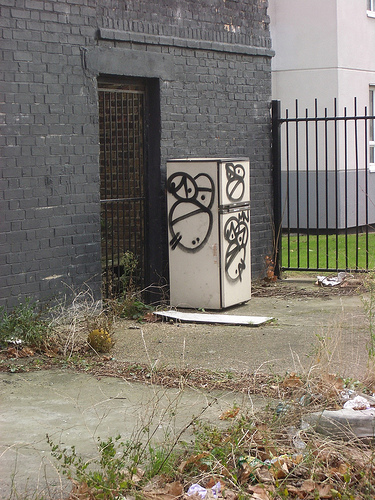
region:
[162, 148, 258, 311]
Discarded refrigerator need door removed to prevent accidental suffocation.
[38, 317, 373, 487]
Overgrown weeds and trash on sidewalks.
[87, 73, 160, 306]
Protective metal door grate.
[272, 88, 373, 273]
Wrought iron gate with bars of staggered height.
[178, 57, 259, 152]
Brick wall painted gray.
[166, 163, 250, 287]
Graffiti on a discarded appliance.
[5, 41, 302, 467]
An outdoor area that is no longer cared for.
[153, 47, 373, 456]
Contrasts in maintenance and upkeep.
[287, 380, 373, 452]
Litter on the ground.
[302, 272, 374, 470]
Discarded trash on sidewalks.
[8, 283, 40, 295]
grey brick on building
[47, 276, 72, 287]
grey brick on building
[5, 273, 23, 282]
grey brick on building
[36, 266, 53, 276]
grey brick on building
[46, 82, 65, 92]
grey brick on building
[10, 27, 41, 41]
grey brick on building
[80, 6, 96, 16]
grey brick on building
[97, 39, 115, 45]
grey brick on building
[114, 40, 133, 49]
grey brick on building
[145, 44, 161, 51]
grey brick on building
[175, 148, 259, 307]
refrigerator against the wall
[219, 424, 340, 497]
leaves on the ground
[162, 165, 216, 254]
graffiti on a refrigerator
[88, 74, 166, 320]
black gate in the doorway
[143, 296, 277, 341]
cardboard on the ground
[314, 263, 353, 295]
paper on the floor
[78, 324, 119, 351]
yellow bag on the floor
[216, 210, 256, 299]
graffiti on the door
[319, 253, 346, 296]
paper on the ground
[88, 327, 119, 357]
a yellow ball on the ground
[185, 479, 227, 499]
discarded paper on the ground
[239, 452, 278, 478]
a green and yellow plastic bag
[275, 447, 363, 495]
a tangle of dead leaves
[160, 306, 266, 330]
a white board on the concrete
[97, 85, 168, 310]
a gated building entrance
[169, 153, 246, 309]
a graffiti covered refridgerator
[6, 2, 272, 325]
a dark blue building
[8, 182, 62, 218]
blue brick in the building wall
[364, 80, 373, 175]
a window on an adjacent building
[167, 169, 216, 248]
black graffiti on the side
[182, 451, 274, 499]
trash mixed into leaves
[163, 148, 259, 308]
an old white refridgerator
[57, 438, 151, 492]
a scraggly green shrub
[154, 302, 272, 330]
a flat white board on the ground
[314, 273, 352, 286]
trash under the fence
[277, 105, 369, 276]
a black iron fence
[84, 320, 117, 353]
an old yellow ball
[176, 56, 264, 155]
a gray brick wall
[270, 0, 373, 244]
an adjacent building